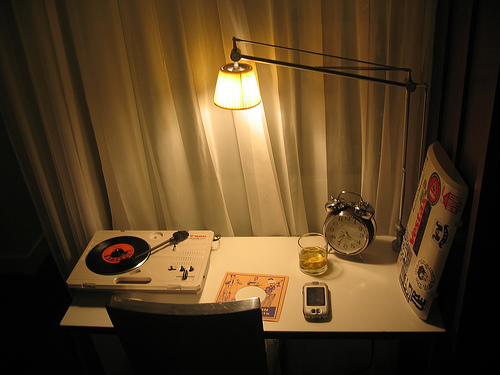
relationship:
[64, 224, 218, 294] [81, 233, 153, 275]
player with record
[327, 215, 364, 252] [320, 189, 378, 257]
face of clock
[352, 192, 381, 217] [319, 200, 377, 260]
bell on clock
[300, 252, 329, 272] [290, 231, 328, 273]
drink in glass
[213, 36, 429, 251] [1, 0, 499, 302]
lamp in front curtains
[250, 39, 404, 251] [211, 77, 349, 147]
pole supporting lamp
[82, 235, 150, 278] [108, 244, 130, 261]
record with red label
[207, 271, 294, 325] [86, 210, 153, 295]
cover for record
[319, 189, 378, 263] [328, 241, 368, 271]
alarm clock on legs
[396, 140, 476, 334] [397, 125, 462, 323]
oval container with pictures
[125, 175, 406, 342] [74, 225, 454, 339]
chair by table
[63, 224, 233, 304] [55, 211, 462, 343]
turntable on desk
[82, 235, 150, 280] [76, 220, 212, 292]
record on turntable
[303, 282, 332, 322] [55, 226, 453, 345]
device on table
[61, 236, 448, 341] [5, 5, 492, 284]
table next to wall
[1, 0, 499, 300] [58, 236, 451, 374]
curtains behind table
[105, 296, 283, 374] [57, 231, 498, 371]
chair at desk